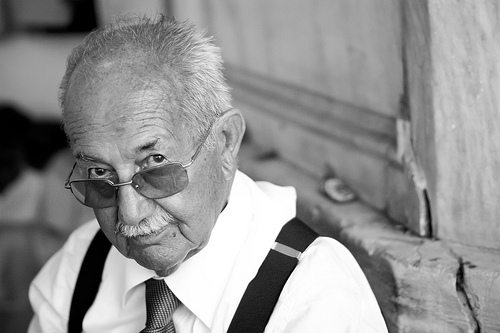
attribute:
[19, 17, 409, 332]
man — old, elderly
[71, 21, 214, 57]
hair — short, gray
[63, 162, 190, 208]
glasses — tinted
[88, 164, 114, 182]
eye — open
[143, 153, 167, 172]
eye — open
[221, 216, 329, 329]
suspender — black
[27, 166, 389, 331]
shirt — white, oxford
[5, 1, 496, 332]
photo — black, white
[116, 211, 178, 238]
mustache — white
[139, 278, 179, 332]
necktie — striped, black, white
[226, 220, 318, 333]
strap — black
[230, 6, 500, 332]
wall — cement, cracked, concrete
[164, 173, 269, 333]
collar — white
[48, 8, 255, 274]
head — balding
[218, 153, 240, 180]
lobe — long